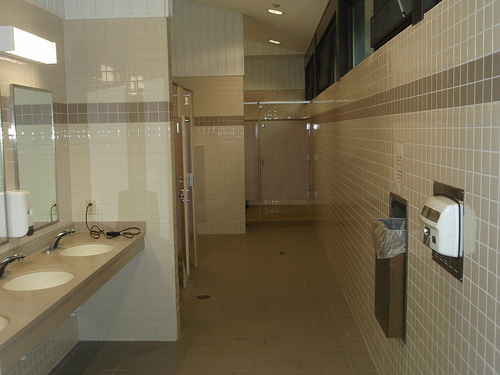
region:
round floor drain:
[193, 291, 210, 303]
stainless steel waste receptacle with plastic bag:
[370, 189, 410, 349]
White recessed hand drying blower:
[417, 177, 468, 287]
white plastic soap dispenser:
[2, 187, 36, 239]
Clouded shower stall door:
[243, 94, 321, 218]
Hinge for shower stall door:
[304, 187, 317, 200]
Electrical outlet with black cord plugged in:
[82, 198, 143, 240]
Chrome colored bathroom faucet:
[43, 227, 78, 253]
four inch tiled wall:
[320, 140, 370, 259]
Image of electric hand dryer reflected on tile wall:
[460, 199, 480, 263]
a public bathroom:
[40, 53, 499, 365]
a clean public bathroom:
[33, 43, 450, 372]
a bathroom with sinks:
[21, 194, 208, 374]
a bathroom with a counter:
[4, 209, 182, 336]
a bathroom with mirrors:
[10, 66, 90, 237]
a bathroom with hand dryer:
[414, 176, 493, 259]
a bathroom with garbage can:
[368, 186, 410, 372]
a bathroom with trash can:
[367, 168, 437, 327]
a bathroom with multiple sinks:
[4, 123, 166, 305]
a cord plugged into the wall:
[67, 193, 167, 266]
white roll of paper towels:
[6, 189, 31, 236]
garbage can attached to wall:
[376, 192, 413, 337]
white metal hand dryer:
[418, 193, 472, 268]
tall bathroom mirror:
[7, 83, 62, 224]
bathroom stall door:
[244, 108, 319, 216]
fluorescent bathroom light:
[3, 23, 65, 68]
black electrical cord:
[82, 203, 139, 238]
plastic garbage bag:
[371, 218, 407, 262]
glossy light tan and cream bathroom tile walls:
[68, 20, 374, 220]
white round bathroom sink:
[61, 239, 118, 258]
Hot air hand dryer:
[417, 195, 457, 258]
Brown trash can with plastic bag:
[369, 212, 400, 335]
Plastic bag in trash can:
[371, 218, 406, 256]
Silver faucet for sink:
[50, 225, 73, 253]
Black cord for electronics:
[80, 206, 142, 240]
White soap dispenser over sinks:
[5, 188, 35, 238]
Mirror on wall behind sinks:
[12, 83, 62, 232]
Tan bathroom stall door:
[167, 117, 191, 266]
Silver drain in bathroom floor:
[197, 291, 210, 299]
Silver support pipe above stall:
[245, 98, 317, 103]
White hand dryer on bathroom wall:
[412, 178, 470, 278]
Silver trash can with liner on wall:
[364, 179, 417, 357]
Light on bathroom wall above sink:
[3, 18, 61, 71]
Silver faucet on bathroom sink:
[49, 219, 79, 252]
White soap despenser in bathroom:
[3, 185, 40, 248]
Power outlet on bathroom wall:
[80, 196, 97, 219]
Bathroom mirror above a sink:
[1, 77, 70, 236]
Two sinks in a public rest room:
[1, 211, 152, 311]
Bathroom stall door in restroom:
[252, 101, 320, 233]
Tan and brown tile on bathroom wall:
[328, 93, 376, 135]